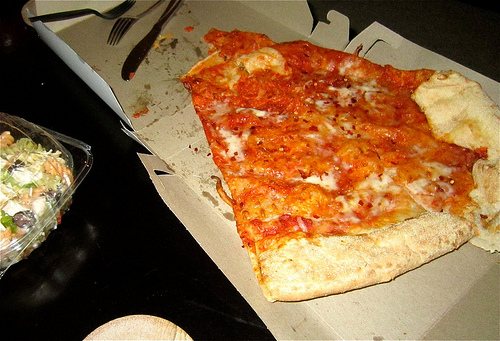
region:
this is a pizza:
[181, 19, 498, 313]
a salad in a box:
[0, 116, 93, 287]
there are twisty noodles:
[0, 128, 31, 160]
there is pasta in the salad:
[0, 117, 97, 274]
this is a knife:
[120, 0, 162, 97]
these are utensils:
[73, 0, 191, 85]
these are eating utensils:
[33, 3, 192, 87]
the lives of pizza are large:
[188, 20, 498, 309]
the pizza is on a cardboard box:
[186, 19, 498, 320]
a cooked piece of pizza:
[162, 19, 494, 290]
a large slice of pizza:
[184, 18, 497, 259]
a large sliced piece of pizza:
[210, 28, 479, 323]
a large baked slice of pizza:
[151, 11, 440, 337]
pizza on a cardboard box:
[117, 19, 404, 322]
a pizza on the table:
[92, 56, 482, 340]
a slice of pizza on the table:
[136, 14, 486, 269]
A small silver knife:
[125, 0, 197, 84]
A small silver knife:
[31, 7, 123, 34]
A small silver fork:
[105, 0, 147, 51]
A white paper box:
[22, 9, 173, 136]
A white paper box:
[232, 0, 350, 32]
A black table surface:
[58, 222, 205, 319]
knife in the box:
[111, 0, 195, 102]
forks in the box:
[36, 1, 167, 43]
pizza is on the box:
[162, 26, 496, 312]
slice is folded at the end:
[181, 8, 307, 95]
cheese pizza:
[183, 28, 361, 277]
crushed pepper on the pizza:
[222, 41, 372, 178]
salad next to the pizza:
[10, 92, 103, 304]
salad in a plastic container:
[0, 94, 106, 310]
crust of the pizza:
[247, 212, 498, 284]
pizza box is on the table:
[23, 2, 498, 339]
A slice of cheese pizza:
[180, 22, 498, 286]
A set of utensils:
[24, 0, 195, 79]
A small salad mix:
[0, 110, 97, 280]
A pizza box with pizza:
[27, 0, 497, 339]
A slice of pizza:
[178, 27, 498, 302]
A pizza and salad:
[0, 27, 498, 337]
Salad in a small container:
[1, 109, 88, 289]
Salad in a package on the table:
[1, 100, 98, 276]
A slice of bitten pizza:
[181, 15, 498, 300]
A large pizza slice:
[183, 23, 498, 291]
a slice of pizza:
[155, 16, 492, 312]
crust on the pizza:
[248, 210, 448, 307]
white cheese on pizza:
[296, 159, 345, 203]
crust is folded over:
[397, 56, 487, 154]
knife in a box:
[116, 0, 188, 108]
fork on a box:
[102, 3, 151, 50]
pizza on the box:
[128, 13, 499, 318]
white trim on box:
[45, 28, 135, 123]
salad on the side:
[3, 103, 91, 265]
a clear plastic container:
[2, 110, 114, 255]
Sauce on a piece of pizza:
[235, 125, 322, 195]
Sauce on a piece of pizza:
[294, 96, 368, 160]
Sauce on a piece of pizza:
[248, 181, 310, 229]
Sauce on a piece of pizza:
[267, 138, 311, 177]